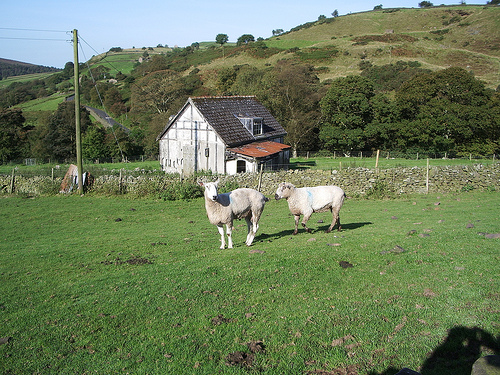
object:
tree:
[0, 109, 28, 165]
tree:
[317, 74, 378, 157]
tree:
[79, 125, 110, 163]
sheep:
[196, 178, 268, 250]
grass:
[1, 189, 500, 374]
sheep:
[272, 182, 351, 235]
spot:
[293, 201, 295, 203]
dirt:
[223, 348, 253, 366]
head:
[196, 177, 219, 202]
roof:
[189, 94, 289, 147]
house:
[154, 95, 287, 178]